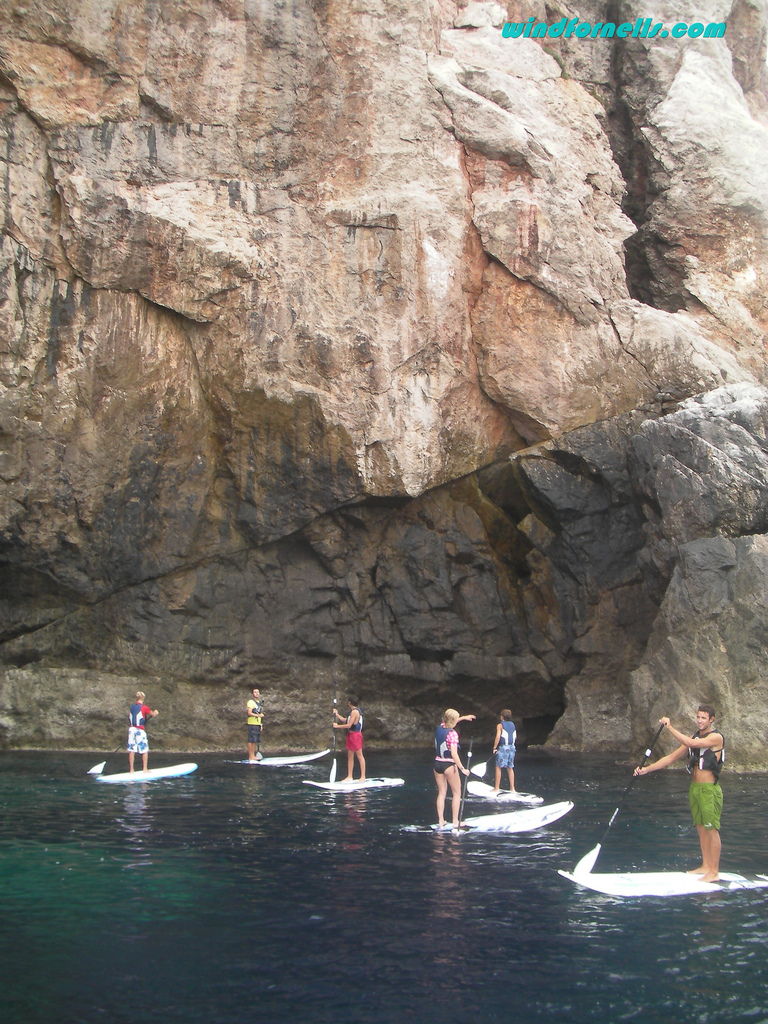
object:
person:
[432, 707, 475, 827]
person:
[493, 709, 517, 792]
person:
[633, 704, 726, 884]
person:
[333, 695, 366, 782]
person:
[247, 688, 264, 760]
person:
[126, 692, 158, 772]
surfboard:
[96, 762, 199, 782]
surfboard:
[235, 748, 331, 765]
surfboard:
[302, 780, 404, 791]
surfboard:
[402, 800, 575, 833]